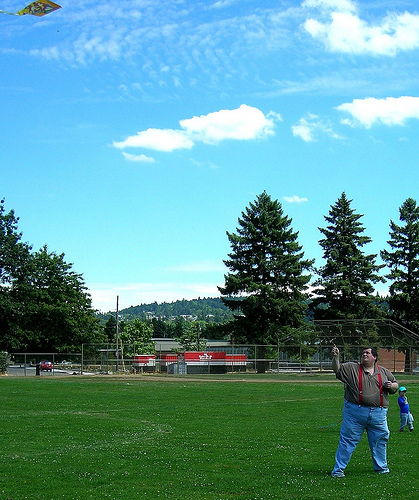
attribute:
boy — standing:
[398, 387, 414, 434]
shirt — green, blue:
[397, 395, 408, 411]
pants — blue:
[400, 412, 413, 430]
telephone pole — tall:
[115, 292, 119, 370]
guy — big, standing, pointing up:
[330, 343, 396, 478]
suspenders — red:
[357, 364, 385, 406]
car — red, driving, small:
[39, 361, 53, 371]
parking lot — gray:
[6, 365, 79, 379]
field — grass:
[2, 375, 416, 499]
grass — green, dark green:
[3, 376, 418, 499]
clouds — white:
[115, 9, 417, 161]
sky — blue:
[1, 1, 418, 303]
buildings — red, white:
[136, 351, 247, 373]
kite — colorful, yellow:
[2, 1, 61, 21]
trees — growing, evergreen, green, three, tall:
[219, 192, 418, 372]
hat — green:
[400, 387, 406, 390]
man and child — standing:
[327, 343, 419, 487]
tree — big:
[218, 192, 316, 372]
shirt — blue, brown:
[336, 359, 389, 404]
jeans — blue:
[327, 405, 401, 478]